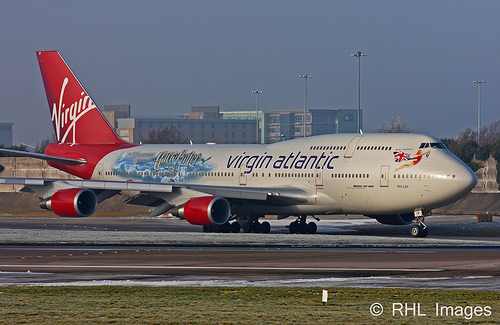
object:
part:
[139, 11, 304, 113]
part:
[98, 290, 137, 321]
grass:
[132, 286, 330, 324]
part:
[37, 218, 150, 283]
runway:
[44, 203, 328, 276]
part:
[50, 181, 102, 215]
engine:
[45, 186, 99, 220]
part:
[235, 222, 244, 237]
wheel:
[230, 222, 240, 233]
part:
[241, 174, 245, 186]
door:
[239, 164, 247, 185]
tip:
[458, 161, 483, 198]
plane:
[0, 46, 477, 241]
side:
[155, 151, 426, 207]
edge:
[13, 148, 86, 162]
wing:
[0, 145, 86, 165]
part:
[10, 141, 53, 163]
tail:
[32, 36, 126, 153]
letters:
[82, 95, 88, 112]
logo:
[226, 151, 339, 174]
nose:
[452, 156, 480, 203]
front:
[415, 225, 423, 240]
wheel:
[409, 225, 429, 238]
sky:
[27, 5, 484, 106]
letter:
[52, 78, 68, 143]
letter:
[59, 103, 66, 129]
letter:
[67, 102, 81, 147]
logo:
[49, 77, 96, 147]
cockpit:
[408, 135, 459, 158]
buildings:
[115, 117, 265, 145]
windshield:
[431, 143, 445, 149]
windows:
[356, 146, 360, 150]